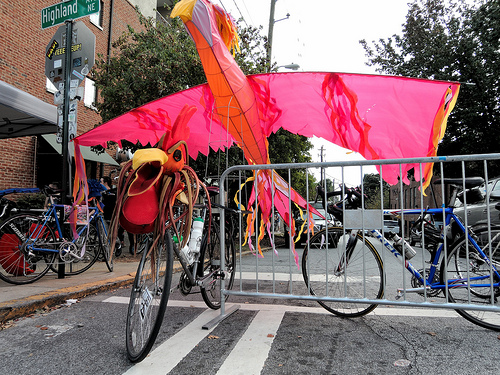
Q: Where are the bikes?
A: In a rack.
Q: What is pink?
A: Kite.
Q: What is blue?
A: Bike.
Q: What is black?
A: Tires.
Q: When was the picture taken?
A: Daytime.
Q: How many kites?
A: One.